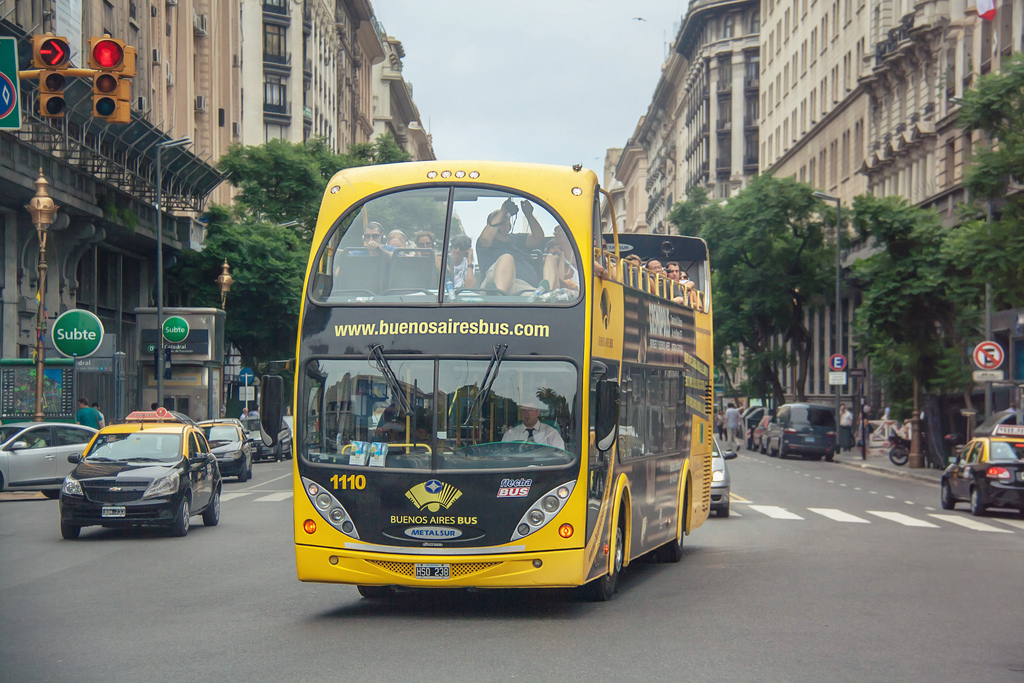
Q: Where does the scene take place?
A: City street.